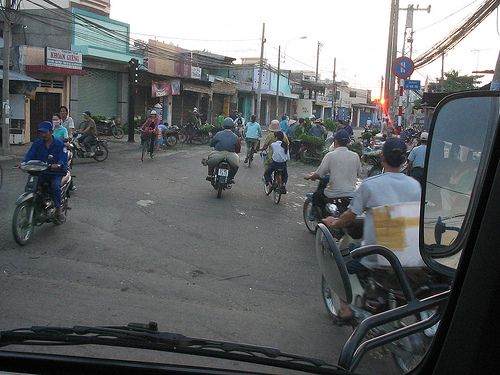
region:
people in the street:
[3, 92, 430, 359]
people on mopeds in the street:
[3, 90, 435, 352]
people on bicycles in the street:
[7, 89, 444, 328]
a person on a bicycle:
[135, 107, 161, 157]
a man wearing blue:
[21, 116, 63, 206]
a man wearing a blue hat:
[34, 120, 52, 134]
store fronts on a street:
[31, 3, 379, 142]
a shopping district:
[5, 10, 400, 155]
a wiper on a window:
[3, 306, 337, 373]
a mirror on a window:
[306, 217, 427, 358]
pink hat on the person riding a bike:
[266, 118, 283, 135]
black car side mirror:
[418, 83, 497, 275]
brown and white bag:
[369, 198, 428, 270]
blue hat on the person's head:
[36, 118, 56, 133]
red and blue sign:
[390, 55, 416, 80]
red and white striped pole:
[395, 76, 407, 143]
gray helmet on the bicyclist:
[220, 113, 236, 129]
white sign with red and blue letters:
[43, 44, 85, 71]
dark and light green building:
[68, 5, 144, 70]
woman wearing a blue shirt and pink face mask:
[49, 112, 70, 145]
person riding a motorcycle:
[207, 109, 249, 204]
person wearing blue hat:
[19, 117, 85, 228]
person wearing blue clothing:
[17, 114, 91, 226]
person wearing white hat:
[138, 109, 165, 153]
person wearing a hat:
[257, 115, 297, 200]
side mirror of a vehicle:
[406, 92, 498, 282]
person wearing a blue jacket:
[242, 110, 264, 165]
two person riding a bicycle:
[254, 118, 300, 210]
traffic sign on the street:
[387, 54, 416, 140]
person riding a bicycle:
[134, 109, 166, 159]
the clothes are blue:
[30, 137, 70, 202]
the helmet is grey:
[219, 113, 238, 127]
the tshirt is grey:
[318, 150, 369, 210]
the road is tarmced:
[131, 203, 236, 296]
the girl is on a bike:
[269, 139, 291, 174]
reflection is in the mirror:
[429, 116, 481, 246]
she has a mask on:
[49, 113, 73, 140]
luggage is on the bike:
[205, 145, 246, 170]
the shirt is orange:
[139, 114, 166, 135]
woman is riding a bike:
[243, 117, 262, 174]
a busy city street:
[17, 7, 477, 361]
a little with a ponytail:
[269, 132, 289, 172]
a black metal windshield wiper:
[31, 318, 321, 373]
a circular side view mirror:
[309, 225, 361, 298]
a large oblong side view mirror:
[414, 91, 496, 265]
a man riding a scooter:
[14, 117, 76, 239]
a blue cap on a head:
[33, 117, 55, 132]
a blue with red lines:
[387, 57, 415, 79]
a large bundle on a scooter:
[209, 149, 246, 167]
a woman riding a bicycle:
[137, 104, 171, 164]